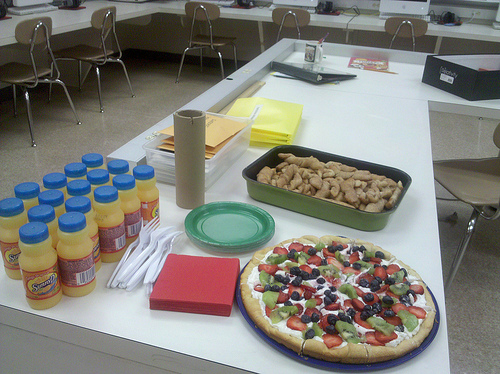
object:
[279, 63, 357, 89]
ring folder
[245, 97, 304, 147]
binder table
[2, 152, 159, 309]
drinks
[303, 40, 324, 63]
white mug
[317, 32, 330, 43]
pens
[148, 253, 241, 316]
napkins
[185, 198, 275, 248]
plates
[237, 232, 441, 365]
slices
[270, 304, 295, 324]
kiwi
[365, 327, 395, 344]
strawberries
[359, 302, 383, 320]
blueberries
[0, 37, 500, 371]
desk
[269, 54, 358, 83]
items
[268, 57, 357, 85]
binder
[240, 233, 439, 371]
dessert pizza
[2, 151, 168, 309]
sunny d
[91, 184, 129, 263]
bottle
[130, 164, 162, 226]
bottle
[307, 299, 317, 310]
kiwi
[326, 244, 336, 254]
blueberry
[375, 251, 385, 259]
blueberry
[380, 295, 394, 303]
blueberry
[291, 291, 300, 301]
blueberry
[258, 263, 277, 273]
strawberry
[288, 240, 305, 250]
strawberry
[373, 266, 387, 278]
strawberry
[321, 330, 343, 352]
strawberry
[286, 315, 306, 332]
strawberry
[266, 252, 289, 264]
kiwi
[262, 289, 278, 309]
kiwi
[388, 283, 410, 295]
kiwi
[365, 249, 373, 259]
kiwi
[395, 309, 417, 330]
kiwi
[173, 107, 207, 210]
tube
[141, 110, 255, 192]
bin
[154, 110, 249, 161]
envelopes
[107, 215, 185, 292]
fork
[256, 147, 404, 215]
chicken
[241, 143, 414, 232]
dish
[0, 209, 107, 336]
bottle table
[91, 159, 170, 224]
bottle table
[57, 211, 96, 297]
bottle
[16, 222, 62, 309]
bottle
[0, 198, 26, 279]
bottle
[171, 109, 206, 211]
towels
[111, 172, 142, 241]
bottle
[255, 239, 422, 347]
toppings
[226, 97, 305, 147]
binder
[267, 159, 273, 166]
interior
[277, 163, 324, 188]
tenders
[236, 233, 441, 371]
plate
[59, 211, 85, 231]
caps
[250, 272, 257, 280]
topping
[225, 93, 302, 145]
folders